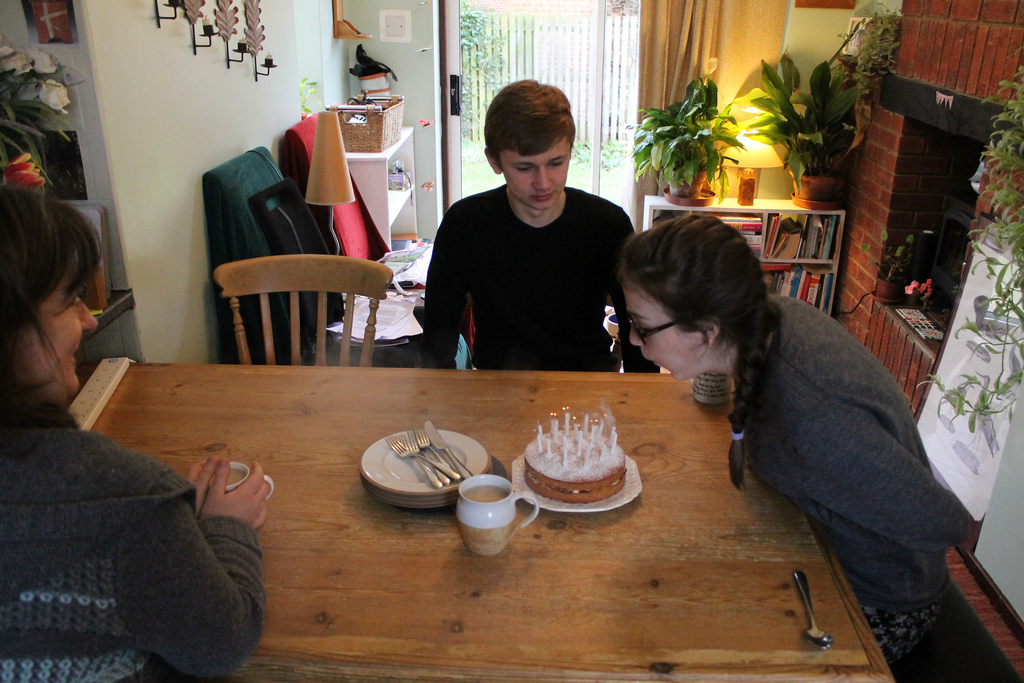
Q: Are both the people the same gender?
A: No, they are both male and female.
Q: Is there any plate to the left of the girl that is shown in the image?
A: Yes, there are plates to the left of the girl.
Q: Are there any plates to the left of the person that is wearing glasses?
A: Yes, there are plates to the left of the girl.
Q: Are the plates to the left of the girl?
A: Yes, the plates are to the left of the girl.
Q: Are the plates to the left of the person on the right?
A: Yes, the plates are to the left of the girl.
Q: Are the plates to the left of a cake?
A: No, the plates are to the left of the girl.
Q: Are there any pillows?
A: No, there are no pillows.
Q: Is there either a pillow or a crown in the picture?
A: No, there are no pillows or crowns.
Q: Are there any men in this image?
A: No, there are no men.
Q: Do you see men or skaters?
A: No, there are no men or skaters.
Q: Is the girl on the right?
A: Yes, the girl is on the right of the image.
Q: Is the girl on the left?
A: No, the girl is on the right of the image.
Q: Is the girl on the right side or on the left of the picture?
A: The girl is on the right of the image.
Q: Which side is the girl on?
A: The girl is on the right of the image.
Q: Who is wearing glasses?
A: The girl is wearing glasses.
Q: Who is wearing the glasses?
A: The girl is wearing glasses.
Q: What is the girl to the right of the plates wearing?
A: The girl is wearing glasses.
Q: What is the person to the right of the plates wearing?
A: The girl is wearing glasses.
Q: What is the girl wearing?
A: The girl is wearing glasses.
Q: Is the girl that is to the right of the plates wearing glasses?
A: Yes, the girl is wearing glasses.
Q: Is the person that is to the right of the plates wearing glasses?
A: Yes, the girl is wearing glasses.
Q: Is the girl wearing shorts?
A: No, the girl is wearing glasses.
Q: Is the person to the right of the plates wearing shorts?
A: No, the girl is wearing glasses.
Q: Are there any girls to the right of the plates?
A: Yes, there is a girl to the right of the plates.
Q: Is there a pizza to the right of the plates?
A: No, there is a girl to the right of the plates.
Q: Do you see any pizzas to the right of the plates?
A: No, there is a girl to the right of the plates.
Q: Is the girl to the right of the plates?
A: Yes, the girl is to the right of the plates.